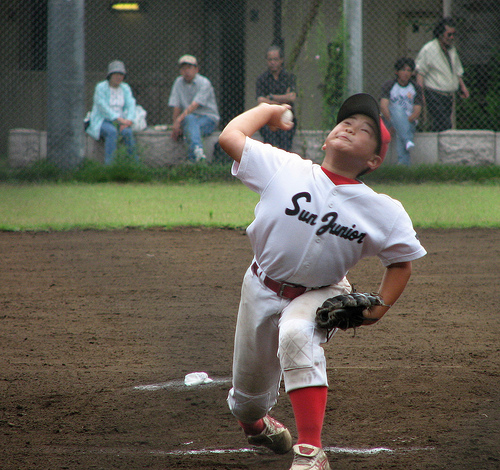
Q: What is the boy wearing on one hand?
A: A baseball glove.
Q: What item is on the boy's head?
A: A baseball cap.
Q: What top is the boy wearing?
A: A white shirt.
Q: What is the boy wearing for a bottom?
A: White pants.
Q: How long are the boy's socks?
A: Long.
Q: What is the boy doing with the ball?
A: Throwing it.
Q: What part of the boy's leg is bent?
A: Knee.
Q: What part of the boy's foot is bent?
A: Ankle.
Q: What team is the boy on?
A: Sun Junior.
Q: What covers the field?
A: Dirt.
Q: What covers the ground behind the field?
A: Grass.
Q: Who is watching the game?
A: Spectators.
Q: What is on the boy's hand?
A: Baseball glove.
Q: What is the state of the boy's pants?
A: Dirty.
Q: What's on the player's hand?
A: Catcher's mitt.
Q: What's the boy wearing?
A: Uniform.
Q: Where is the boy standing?
A: Mound of soil.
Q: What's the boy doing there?
A: Throwing ball.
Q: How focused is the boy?
A: Very focused.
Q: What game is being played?
A: Baseball.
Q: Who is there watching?
A: Spectators.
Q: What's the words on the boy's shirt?
A: Sun Junior.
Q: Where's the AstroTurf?
A: On field.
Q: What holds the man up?
A: Legs.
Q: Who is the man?
A: Ball player.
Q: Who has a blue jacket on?
A: Woman sitting.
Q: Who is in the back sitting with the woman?
A: A man.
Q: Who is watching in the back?
A: Spectators.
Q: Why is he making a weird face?
A: Pitching the ball.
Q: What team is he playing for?
A: Sun junior.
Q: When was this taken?
A: During a game.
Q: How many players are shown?
A: One.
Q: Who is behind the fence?
A: Spectators.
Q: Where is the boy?
A: On the field.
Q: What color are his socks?
A: Red.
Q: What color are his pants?
A: White.